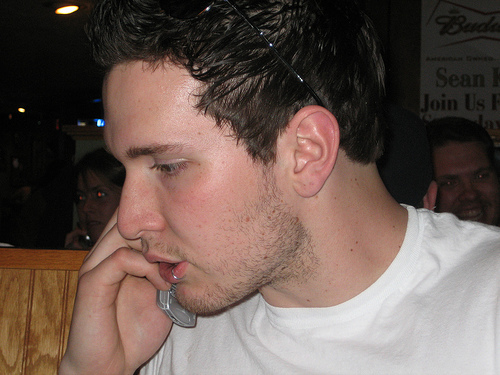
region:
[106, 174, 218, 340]
man on a cellphone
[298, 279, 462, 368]
man wearing a white tee shirt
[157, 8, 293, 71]
man wearing sunglasses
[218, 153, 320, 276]
man with a bird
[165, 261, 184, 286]
man with a pierced lip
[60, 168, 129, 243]
woman on a cellphone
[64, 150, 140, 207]
woman with brown hair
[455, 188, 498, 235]
man with a smile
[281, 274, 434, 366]
man with a white shirt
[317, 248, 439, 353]
man wearing a white shirt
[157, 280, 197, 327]
grey small cell phone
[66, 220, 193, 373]
hand holding cell phone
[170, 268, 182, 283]
silver ring in lip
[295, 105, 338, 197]
ear of a man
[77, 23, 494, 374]
man sitting in a restaurant booth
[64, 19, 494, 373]
man with dark hair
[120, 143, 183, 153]
dark eyebrow of man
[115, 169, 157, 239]
nose of man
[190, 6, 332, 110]
sunglasses on man's head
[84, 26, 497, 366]
man is wearing a white shirt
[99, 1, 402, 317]
the head of a man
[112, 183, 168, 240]
the nose of a man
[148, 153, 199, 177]
the eye of a man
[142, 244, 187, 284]
the mouth of a man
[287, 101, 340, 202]
the ear of a man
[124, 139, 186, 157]
the eyebrow of a man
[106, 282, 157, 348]
the palm of a man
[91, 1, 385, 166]
the hair of a man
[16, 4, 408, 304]
a man with sunglasses on his head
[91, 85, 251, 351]
a man talking on a cell phone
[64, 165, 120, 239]
woman in background smoking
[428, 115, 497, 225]
man in background smiling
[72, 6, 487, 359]
man wearing a white shirt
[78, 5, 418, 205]
man with sunglasses on his head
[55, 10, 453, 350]
man talking on cellphone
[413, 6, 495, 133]
Budweiser advertisement in background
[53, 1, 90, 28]
semi bright ceiling light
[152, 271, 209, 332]
old grey cellphone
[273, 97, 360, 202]
man's pink ear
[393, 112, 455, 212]
back of man's head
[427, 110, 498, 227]
man smiling in the background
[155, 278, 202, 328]
silver cellphone in man's hand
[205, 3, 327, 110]
sun glass arm on man's head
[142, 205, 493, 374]
white cotton tee shirt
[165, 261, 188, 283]
round metal lip ring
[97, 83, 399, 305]
small brown freckles on man's head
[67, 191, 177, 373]
right hand holding a cellphone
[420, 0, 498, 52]
Budweiser bow tie advertisement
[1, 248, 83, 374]
wooden booth seating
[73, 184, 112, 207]
woman's red eyes in the background